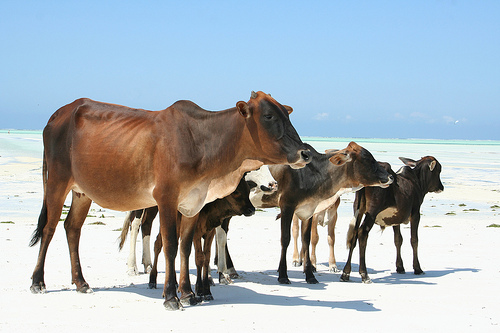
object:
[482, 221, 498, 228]
plants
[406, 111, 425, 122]
clouds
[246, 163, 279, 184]
face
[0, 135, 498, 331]
beach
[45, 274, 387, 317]
shadows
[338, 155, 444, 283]
cows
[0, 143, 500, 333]
field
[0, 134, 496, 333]
snow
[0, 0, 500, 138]
sky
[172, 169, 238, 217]
cow chest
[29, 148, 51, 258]
tail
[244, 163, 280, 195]
head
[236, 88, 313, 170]
head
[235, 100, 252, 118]
ears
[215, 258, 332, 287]
shadows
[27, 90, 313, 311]
cow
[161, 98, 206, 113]
bump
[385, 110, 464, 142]
mountains